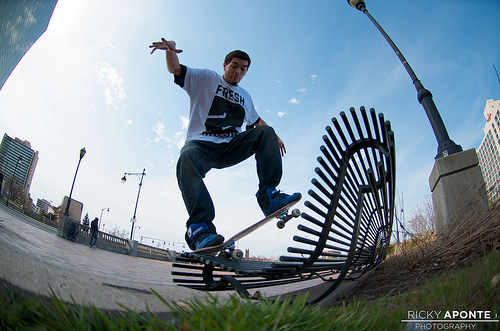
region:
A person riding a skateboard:
[119, 20, 304, 268]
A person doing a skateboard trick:
[133, 23, 311, 267]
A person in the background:
[88, 215, 103, 250]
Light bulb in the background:
[116, 172, 131, 183]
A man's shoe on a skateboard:
[179, 215, 226, 249]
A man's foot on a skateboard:
[258, 182, 303, 214]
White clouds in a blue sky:
[275, 8, 326, 108]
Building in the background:
[0, 124, 47, 215]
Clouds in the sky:
[94, 59, 134, 113]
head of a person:
[203, 41, 265, 92]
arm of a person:
[160, 48, 210, 95]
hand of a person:
[132, 12, 213, 72]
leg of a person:
[175, 153, 239, 215]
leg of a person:
[252, 123, 293, 187]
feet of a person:
[180, 223, 242, 265]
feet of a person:
[249, 195, 314, 219]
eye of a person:
[230, 58, 254, 66]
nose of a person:
[232, 63, 256, 80]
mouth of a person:
[222, 72, 246, 86]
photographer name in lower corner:
[395, 299, 499, 329]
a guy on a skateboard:
[140, 5, 316, 268]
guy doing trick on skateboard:
[126, 17, 309, 315]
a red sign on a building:
[471, 105, 498, 122]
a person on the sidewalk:
[75, 207, 129, 279]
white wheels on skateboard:
[227, 207, 312, 266]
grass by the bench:
[105, 283, 497, 320]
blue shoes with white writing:
[158, 189, 340, 281]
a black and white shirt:
[177, 48, 296, 162]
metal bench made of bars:
[167, 104, 398, 316]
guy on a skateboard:
[146, 32, 301, 264]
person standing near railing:
[86, 216, 100, 248]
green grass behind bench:
[5, 250, 498, 329]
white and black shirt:
[175, 62, 259, 145]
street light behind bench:
[343, 0, 466, 162]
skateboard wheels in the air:
[274, 206, 304, 232]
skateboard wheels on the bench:
[218, 246, 245, 259]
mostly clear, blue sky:
[0, 0, 498, 257]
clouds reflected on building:
[0, 0, 56, 90]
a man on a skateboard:
[142, 20, 316, 261]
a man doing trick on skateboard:
[132, 19, 342, 281]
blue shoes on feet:
[172, 175, 323, 256]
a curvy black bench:
[152, 86, 446, 329]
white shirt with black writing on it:
[167, 53, 262, 145]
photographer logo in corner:
[392, 302, 497, 329]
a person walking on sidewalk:
[58, 204, 120, 274]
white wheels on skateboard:
[201, 198, 308, 265]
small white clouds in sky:
[66, 49, 329, 161]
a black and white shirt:
[145, 37, 285, 157]